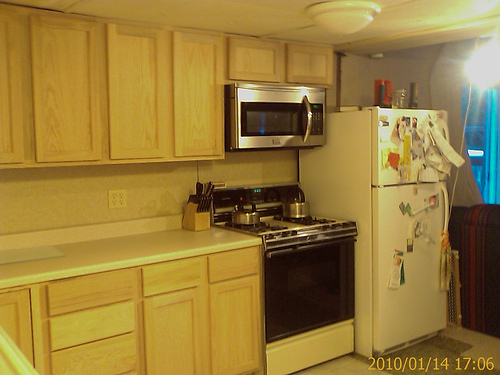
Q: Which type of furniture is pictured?
A: The furniture is cabinets.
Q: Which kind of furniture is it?
A: The pieces of furniture are cabinets.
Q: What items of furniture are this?
A: These are cabinets.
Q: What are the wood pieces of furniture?
A: The pieces of furniture are cabinets.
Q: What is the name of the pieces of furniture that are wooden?
A: The pieces of furniture are cabinets.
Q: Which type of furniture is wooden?
A: The furniture is cabinets.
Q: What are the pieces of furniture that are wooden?
A: The pieces of furniture are cabinets.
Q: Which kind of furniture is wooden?
A: The furniture is cabinets.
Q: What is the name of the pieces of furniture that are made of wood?
A: The pieces of furniture are cabinets.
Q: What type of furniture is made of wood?
A: The furniture is cabinets.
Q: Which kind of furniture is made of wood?
A: The furniture is cabinets.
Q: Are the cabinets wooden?
A: Yes, the cabinets are wooden.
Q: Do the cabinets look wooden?
A: Yes, the cabinets are wooden.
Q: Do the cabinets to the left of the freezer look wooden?
A: Yes, the cabinets are wooden.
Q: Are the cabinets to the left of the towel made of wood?
A: Yes, the cabinets are made of wood.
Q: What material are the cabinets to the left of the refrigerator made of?
A: The cabinets are made of wood.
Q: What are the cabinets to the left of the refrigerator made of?
A: The cabinets are made of wood.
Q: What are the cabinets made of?
A: The cabinets are made of wood.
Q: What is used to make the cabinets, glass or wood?
A: The cabinets are made of wood.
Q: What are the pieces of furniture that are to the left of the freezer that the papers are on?
A: The pieces of furniture are cabinets.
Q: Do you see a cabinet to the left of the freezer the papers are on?
A: Yes, there are cabinets to the left of the fridge.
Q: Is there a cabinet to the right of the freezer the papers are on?
A: No, the cabinets are to the left of the fridge.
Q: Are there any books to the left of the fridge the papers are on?
A: No, there are cabinets to the left of the fridge.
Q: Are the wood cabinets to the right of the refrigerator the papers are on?
A: No, the cabinets are to the left of the fridge.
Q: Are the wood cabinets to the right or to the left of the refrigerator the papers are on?
A: The cabinets are to the left of the fridge.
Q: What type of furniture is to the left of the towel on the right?
A: The pieces of furniture are cabinets.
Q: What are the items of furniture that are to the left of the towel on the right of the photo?
A: The pieces of furniture are cabinets.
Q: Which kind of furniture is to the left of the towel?
A: The pieces of furniture are cabinets.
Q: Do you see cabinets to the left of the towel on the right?
A: Yes, there are cabinets to the left of the towel.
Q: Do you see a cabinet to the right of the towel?
A: No, the cabinets are to the left of the towel.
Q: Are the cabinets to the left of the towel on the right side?
A: Yes, the cabinets are to the left of the towel.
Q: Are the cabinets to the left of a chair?
A: No, the cabinets are to the left of the towel.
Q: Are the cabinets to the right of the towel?
A: No, the cabinets are to the left of the towel.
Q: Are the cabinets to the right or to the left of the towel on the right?
A: The cabinets are to the left of the towel.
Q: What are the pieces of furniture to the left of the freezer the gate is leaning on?
A: The pieces of furniture are cabinets.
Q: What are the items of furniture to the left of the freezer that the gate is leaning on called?
A: The pieces of furniture are cabinets.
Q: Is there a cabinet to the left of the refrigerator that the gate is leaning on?
A: Yes, there are cabinets to the left of the refrigerator.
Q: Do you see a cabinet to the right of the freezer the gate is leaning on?
A: No, the cabinets are to the left of the fridge.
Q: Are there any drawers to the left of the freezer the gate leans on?
A: No, there are cabinets to the left of the fridge.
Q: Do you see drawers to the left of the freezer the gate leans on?
A: No, there are cabinets to the left of the fridge.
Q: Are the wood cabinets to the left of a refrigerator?
A: Yes, the cabinets are to the left of a refrigerator.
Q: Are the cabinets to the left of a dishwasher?
A: No, the cabinets are to the left of a refrigerator.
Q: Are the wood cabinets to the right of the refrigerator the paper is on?
A: No, the cabinets are to the left of the refrigerator.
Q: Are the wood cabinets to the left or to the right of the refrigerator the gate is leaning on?
A: The cabinets are to the left of the fridge.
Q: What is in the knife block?
A: The knives are in the knife block.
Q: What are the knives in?
A: The knives are in the knife block.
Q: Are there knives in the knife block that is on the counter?
A: Yes, there are knives in the knife block.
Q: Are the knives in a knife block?
A: Yes, the knives are in a knife block.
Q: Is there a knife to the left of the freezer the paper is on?
A: Yes, there are knives to the left of the refrigerator.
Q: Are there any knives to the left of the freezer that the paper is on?
A: Yes, there are knives to the left of the refrigerator.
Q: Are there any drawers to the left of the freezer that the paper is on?
A: No, there are knives to the left of the refrigerator.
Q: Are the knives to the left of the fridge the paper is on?
A: Yes, the knives are to the left of the fridge.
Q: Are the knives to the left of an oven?
A: No, the knives are to the left of the fridge.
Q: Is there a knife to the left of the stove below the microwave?
A: Yes, there are knives to the left of the stove.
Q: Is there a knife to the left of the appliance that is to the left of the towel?
A: Yes, there are knives to the left of the stove.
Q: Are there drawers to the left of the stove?
A: No, there are knives to the left of the stove.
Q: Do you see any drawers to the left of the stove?
A: No, there are knives to the left of the stove.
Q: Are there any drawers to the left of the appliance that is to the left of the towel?
A: No, there are knives to the left of the stove.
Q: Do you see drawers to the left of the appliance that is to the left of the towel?
A: No, there are knives to the left of the stove.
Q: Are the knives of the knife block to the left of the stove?
A: Yes, the knives are to the left of the stove.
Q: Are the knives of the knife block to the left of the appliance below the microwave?
A: Yes, the knives are to the left of the stove.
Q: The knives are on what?
A: The knives are on the counter.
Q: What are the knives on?
A: The knives are on the counter.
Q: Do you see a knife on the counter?
A: Yes, there are knives on the counter.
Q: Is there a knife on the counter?
A: Yes, there are knives on the counter.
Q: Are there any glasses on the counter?
A: No, there are knives on the counter.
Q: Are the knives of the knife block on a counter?
A: Yes, the knives are on a counter.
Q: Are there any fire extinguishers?
A: No, there are no fire extinguishers.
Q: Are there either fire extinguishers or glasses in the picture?
A: No, there are no fire extinguishers or glasses.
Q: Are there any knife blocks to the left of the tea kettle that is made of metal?
A: Yes, there is a knife block to the left of the tea kettle.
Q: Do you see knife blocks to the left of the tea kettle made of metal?
A: Yes, there is a knife block to the left of the tea kettle.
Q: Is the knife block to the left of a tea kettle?
A: Yes, the knife block is to the left of a tea kettle.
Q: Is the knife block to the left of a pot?
A: No, the knife block is to the left of a tea kettle.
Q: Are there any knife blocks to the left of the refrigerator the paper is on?
A: Yes, there is a knife block to the left of the refrigerator.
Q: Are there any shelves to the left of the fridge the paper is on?
A: No, there is a knife block to the left of the freezer.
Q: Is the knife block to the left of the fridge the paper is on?
A: Yes, the knife block is to the left of the freezer.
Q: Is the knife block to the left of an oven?
A: No, the knife block is to the left of the freezer.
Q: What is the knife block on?
A: The knife block is on the counter.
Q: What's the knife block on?
A: The knife block is on the counter.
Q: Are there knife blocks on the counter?
A: Yes, there is a knife block on the counter.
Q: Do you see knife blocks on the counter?
A: Yes, there is a knife block on the counter.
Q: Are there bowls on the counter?
A: No, there is a knife block on the counter.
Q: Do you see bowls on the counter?
A: No, there is a knife block on the counter.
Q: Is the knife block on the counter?
A: Yes, the knife block is on the counter.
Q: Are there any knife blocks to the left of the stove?
A: Yes, there is a knife block to the left of the stove.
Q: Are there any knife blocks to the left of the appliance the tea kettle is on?
A: Yes, there is a knife block to the left of the stove.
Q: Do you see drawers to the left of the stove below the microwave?
A: No, there is a knife block to the left of the stove.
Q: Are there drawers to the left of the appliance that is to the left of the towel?
A: No, there is a knife block to the left of the stove.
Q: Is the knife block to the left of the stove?
A: Yes, the knife block is to the left of the stove.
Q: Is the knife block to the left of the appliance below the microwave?
A: Yes, the knife block is to the left of the stove.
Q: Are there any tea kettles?
A: Yes, there is a tea kettle.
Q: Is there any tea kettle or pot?
A: Yes, there is a tea kettle.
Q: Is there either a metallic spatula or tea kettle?
A: Yes, there is a metal tea kettle.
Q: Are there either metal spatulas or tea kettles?
A: Yes, there is a metal tea kettle.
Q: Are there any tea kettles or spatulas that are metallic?
A: Yes, the tea kettle is metallic.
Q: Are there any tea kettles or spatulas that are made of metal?
A: Yes, the tea kettle is made of metal.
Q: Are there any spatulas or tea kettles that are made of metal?
A: Yes, the tea kettle is made of metal.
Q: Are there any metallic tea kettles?
A: Yes, there is a metal tea kettle.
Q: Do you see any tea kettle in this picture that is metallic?
A: Yes, there is a tea kettle that is metallic.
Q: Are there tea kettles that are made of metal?
A: Yes, there is a tea kettle that is made of metal.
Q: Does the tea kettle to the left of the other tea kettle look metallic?
A: Yes, the tea kettle is metallic.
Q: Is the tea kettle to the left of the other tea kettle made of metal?
A: Yes, the tea kettle is made of metal.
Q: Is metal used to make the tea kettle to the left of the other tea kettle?
A: Yes, the tea kettle is made of metal.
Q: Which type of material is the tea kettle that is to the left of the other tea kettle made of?
A: The tea kettle is made of metal.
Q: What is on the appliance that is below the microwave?
A: The tea kettle is on the stove.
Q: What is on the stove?
A: The tea kettle is on the stove.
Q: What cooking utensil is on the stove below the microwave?
A: The cooking utensil is a tea kettle.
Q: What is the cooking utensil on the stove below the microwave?
A: The cooking utensil is a tea kettle.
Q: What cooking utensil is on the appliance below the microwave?
A: The cooking utensil is a tea kettle.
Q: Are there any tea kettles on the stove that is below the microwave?
A: Yes, there is a tea kettle on the stove.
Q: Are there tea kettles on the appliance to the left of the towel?
A: Yes, there is a tea kettle on the stove.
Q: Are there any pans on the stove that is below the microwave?
A: No, there is a tea kettle on the stove.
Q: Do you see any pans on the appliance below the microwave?
A: No, there is a tea kettle on the stove.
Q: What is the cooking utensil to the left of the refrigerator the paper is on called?
A: The cooking utensil is a tea kettle.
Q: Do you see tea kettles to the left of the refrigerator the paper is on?
A: Yes, there is a tea kettle to the left of the refrigerator.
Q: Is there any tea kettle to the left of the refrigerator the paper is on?
A: Yes, there is a tea kettle to the left of the refrigerator.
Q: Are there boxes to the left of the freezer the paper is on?
A: No, there is a tea kettle to the left of the refrigerator.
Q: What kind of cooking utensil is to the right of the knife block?
A: The cooking utensil is a tea kettle.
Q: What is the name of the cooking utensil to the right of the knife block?
A: The cooking utensil is a tea kettle.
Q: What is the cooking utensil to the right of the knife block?
A: The cooking utensil is a tea kettle.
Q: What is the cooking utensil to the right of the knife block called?
A: The cooking utensil is a tea kettle.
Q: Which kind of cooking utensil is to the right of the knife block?
A: The cooking utensil is a tea kettle.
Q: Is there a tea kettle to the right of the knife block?
A: Yes, there is a tea kettle to the right of the knife block.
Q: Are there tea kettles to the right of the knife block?
A: Yes, there is a tea kettle to the right of the knife block.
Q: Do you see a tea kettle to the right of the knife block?
A: Yes, there is a tea kettle to the right of the knife block.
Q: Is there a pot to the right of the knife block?
A: No, there is a tea kettle to the right of the knife block.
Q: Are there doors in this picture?
A: Yes, there is a door.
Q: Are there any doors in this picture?
A: Yes, there is a door.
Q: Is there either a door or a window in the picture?
A: Yes, there is a door.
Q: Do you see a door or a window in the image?
A: Yes, there is a door.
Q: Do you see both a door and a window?
A: Yes, there are both a door and a window.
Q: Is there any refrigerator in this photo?
A: Yes, there is a refrigerator.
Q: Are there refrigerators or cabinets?
A: Yes, there is a refrigerator.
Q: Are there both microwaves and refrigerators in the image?
A: Yes, there are both a refrigerator and a microwave.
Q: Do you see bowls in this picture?
A: No, there are no bowls.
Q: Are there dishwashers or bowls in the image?
A: No, there are no bowls or dishwashers.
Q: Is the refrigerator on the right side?
A: Yes, the refrigerator is on the right of the image.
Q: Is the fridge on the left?
A: No, the fridge is on the right of the image.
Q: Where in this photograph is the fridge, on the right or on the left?
A: The fridge is on the right of the image.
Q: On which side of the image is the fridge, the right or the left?
A: The fridge is on the right of the image.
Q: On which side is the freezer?
A: The freezer is on the right of the image.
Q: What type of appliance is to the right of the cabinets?
A: The appliance is a refrigerator.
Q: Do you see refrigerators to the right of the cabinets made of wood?
A: Yes, there is a refrigerator to the right of the cabinets.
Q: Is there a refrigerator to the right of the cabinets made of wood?
A: Yes, there is a refrigerator to the right of the cabinets.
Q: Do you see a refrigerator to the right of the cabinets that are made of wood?
A: Yes, there is a refrigerator to the right of the cabinets.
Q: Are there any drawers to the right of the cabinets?
A: No, there is a refrigerator to the right of the cabinets.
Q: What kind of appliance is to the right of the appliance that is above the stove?
A: The appliance is a refrigerator.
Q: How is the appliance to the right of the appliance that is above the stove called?
A: The appliance is a refrigerator.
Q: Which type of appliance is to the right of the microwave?
A: The appliance is a refrigerator.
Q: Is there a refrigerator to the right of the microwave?
A: Yes, there is a refrigerator to the right of the microwave.